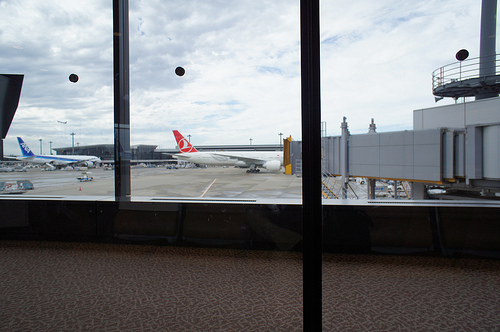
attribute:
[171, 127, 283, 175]
plane — white, red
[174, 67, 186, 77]
circle — black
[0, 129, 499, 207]
airrport — rectangle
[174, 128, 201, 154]
tail — red, white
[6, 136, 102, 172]
plane — blue, white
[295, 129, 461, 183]
fence — metal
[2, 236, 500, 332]
pattern — brown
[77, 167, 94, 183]
car — small, driving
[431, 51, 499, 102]
balcony — fenced, black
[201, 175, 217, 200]
line — drawn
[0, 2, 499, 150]
sky — blue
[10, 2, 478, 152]
clouds — white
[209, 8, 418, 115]
patches — small, blue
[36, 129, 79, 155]
street lamps — tall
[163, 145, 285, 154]
bridge — long, gray